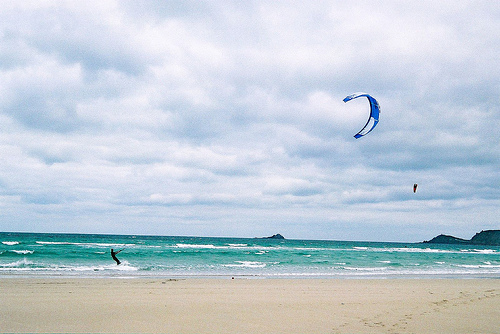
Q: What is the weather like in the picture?
A: It is cloudy.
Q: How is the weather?
A: It is cloudy.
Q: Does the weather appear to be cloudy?
A: Yes, it is cloudy.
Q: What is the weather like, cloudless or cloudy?
A: It is cloudy.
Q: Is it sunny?
A: No, it is cloudy.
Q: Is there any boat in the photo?
A: No, there are no boats.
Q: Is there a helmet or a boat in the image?
A: No, there are no boats or helmets.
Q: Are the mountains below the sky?
A: Yes, the mountains are below the sky.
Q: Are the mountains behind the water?
A: Yes, the mountains are behind the water.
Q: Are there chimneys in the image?
A: No, there are no chimneys.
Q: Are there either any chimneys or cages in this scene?
A: No, there are no chimneys or cages.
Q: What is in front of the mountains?
A: The water is in front of the mountains.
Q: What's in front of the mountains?
A: The water is in front of the mountains.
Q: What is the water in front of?
A: The water is in front of the mountains.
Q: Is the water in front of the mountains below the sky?
A: Yes, the water is in front of the mountains.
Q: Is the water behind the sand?
A: Yes, the water is behind the sand.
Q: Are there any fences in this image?
A: No, there are no fences.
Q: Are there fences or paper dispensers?
A: No, there are no fences or paper dispensers.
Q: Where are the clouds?
A: The clouds are in the sky.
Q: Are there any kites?
A: Yes, there is a kite.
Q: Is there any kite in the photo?
A: Yes, there is a kite.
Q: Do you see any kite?
A: Yes, there is a kite.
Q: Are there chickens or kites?
A: Yes, there is a kite.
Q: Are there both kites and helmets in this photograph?
A: No, there is a kite but no helmets.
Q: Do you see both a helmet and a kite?
A: No, there is a kite but no helmets.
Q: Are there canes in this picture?
A: No, there are no canes.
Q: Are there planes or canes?
A: No, there are no canes or planes.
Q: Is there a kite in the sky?
A: Yes, there is a kite in the sky.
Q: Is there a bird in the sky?
A: No, there is a kite in the sky.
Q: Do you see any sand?
A: Yes, there is sand.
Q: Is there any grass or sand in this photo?
A: Yes, there is sand.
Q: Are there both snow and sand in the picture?
A: No, there is sand but no snow.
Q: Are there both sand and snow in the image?
A: No, there is sand but no snow.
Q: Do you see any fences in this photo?
A: No, there are no fences.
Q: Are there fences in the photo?
A: No, there are no fences.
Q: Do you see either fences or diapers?
A: No, there are no fences or diapers.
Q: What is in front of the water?
A: The sand is in front of the water.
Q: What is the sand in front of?
A: The sand is in front of the water.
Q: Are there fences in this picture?
A: No, there are no fences.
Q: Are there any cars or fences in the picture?
A: No, there are no fences or cars.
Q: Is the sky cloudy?
A: Yes, the sky is cloudy.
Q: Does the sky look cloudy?
A: Yes, the sky is cloudy.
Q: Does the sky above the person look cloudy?
A: Yes, the sky is cloudy.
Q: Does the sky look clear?
A: No, the sky is cloudy.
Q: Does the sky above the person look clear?
A: No, the sky is cloudy.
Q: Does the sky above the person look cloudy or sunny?
A: The sky is cloudy.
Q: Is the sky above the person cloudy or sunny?
A: The sky is cloudy.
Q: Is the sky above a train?
A: No, the sky is above the person.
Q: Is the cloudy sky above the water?
A: Yes, the sky is above the water.